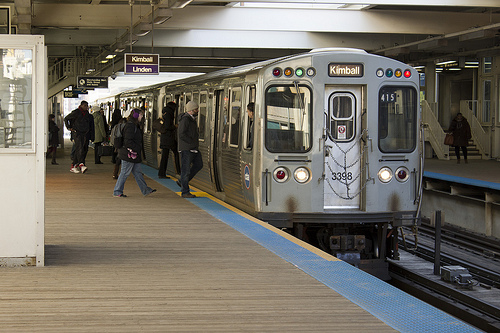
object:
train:
[90, 47, 425, 281]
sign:
[123, 53, 161, 76]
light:
[295, 170, 308, 181]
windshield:
[263, 85, 316, 156]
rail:
[388, 259, 500, 321]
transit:
[61, 43, 428, 287]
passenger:
[175, 100, 204, 198]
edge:
[146, 165, 488, 332]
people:
[112, 108, 158, 199]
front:
[261, 52, 421, 213]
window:
[227, 85, 243, 148]